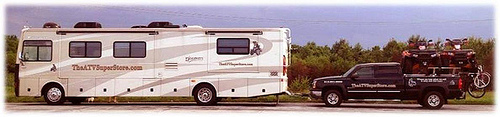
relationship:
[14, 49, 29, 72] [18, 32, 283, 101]
mirror on bus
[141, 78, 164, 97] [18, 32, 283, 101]
spot on bus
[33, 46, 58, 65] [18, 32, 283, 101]
driver on bus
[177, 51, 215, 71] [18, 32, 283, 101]
words on bus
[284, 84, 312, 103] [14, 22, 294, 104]
tow bar between rv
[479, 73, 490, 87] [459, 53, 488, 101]
wheel on bicycle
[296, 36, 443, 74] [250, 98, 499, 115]
forest along road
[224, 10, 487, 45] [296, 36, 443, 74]
sky above forest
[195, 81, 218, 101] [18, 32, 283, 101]
wheel on bus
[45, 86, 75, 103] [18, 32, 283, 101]
wheel on bus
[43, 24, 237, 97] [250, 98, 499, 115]
rv on road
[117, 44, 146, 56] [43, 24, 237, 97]
window on rv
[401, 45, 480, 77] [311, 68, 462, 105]
atv on truck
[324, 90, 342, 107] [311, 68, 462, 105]
wheel on truck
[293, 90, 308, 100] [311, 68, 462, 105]
connector between truck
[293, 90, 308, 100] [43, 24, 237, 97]
connector between rv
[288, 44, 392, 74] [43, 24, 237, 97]
trees by rv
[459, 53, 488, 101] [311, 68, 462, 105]
bicycle on truck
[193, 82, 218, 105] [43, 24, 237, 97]
wheel of rv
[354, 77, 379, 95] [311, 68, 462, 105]
door of truck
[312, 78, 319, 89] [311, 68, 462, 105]
lights on truck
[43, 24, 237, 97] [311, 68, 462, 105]
rv pulling truck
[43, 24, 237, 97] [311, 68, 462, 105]
rv towing truck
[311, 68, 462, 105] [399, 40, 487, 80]
truck carrying four wheelers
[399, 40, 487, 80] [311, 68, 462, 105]
four wheelers on truck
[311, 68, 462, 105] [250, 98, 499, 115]
truck on road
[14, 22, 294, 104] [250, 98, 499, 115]
rv on road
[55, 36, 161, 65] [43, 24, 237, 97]
windows on rv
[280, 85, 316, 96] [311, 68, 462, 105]
chain connecting truck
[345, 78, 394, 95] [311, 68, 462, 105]
writing on truck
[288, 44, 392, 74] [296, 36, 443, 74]
trees in forest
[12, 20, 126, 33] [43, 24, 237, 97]
lights on van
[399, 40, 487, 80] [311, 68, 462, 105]
bike on truck